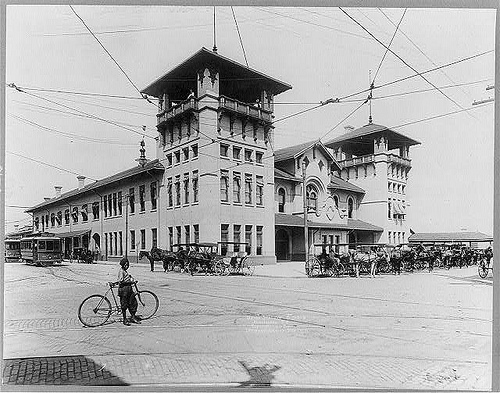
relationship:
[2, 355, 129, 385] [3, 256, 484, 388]
shadow casted on road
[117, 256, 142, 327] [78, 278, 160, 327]
man next to bicycle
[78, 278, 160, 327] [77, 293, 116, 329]
bicycle has wheel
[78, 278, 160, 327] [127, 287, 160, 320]
bicycle has wheel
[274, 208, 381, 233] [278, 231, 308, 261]
awning over doorway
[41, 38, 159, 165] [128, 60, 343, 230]
wires outside building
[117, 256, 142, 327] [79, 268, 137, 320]
man near bike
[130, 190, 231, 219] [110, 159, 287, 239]
windows on building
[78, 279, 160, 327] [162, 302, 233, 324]
bicycle on road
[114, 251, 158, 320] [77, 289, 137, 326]
man in front of bicycle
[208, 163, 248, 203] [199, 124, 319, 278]
window on building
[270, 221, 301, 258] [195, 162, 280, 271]
door on building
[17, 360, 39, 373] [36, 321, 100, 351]
brick on ground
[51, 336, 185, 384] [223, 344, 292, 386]
shadow on ground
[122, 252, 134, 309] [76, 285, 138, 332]
woman on side of bicycle